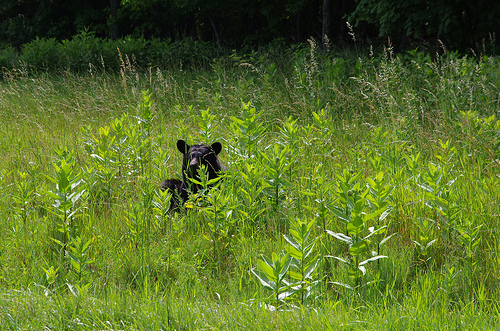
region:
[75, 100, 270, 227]
bear in the field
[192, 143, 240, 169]
the bear is black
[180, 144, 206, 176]
head of the bear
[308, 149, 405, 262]
the weeds are tall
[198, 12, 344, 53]
the trees are dark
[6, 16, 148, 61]
the bushes are short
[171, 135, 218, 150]
ears of hte bear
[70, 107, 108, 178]
leaves on the weeds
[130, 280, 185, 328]
some grass is tall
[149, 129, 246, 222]
black bear in grass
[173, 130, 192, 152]
ear of black bear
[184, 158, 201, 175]
nose of black bear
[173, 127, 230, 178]
head of black bear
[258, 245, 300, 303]
green plant in grass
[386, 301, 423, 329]
bunches of green grass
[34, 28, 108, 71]
several green bushes in grass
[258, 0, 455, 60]
several trees with green leafs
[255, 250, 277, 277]
green leaf on plant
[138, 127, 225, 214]
black bear in the tall grass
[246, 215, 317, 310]
wide leaves on the plant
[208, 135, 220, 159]
ear on the bear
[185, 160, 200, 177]
muzzle on the bear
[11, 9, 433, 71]
trees behind the bear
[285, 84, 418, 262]
very tall grass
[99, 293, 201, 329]
green grass in front of the bear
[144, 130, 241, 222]
bear is partially hidden by grass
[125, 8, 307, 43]
trees are in shadow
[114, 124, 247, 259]
bear is hiding in the grass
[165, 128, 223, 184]
head of a bear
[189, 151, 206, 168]
nose of a bear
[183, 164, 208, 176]
mouth of a bear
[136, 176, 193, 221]
body of a bear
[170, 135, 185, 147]
ear of a bear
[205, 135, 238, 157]
ear of a bear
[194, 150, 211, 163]
eye of a bear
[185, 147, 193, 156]
eye of a bear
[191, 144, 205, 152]
hair of a bear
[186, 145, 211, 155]
forehead of a bear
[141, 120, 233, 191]
A back bear in the field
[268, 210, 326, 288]
A small green plant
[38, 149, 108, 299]
A small green plant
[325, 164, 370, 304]
A small green plant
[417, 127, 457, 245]
A small green plant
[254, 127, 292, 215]
A small green plant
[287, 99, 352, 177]
A small green plant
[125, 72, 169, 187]
A small green plant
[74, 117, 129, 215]
A small green plant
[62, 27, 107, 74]
A small green plant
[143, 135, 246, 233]
black bear laying in the field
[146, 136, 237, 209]
black bear laying in the field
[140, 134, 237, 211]
black bear laying in the field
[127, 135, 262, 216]
black bear laying in the field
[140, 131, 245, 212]
black bear laying in the field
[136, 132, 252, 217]
black bear laying in the field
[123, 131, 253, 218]
black bear laying in the field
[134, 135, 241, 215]
black bear laying in the field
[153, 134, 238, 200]
black bear laying in the field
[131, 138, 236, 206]
black bear laying in the field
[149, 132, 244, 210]
bear in the weeds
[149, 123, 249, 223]
the bear is black